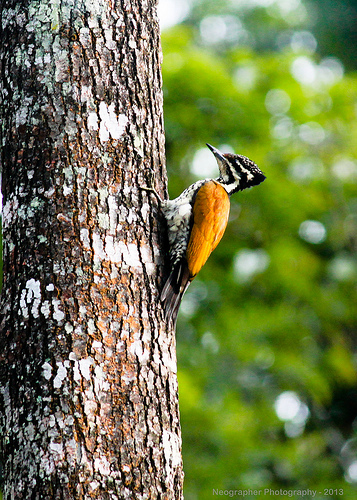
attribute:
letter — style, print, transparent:
[236, 489, 243, 497]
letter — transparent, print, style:
[210, 486, 218, 497]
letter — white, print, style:
[210, 486, 266, 498]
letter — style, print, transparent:
[273, 489, 280, 496]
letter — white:
[223, 489, 228, 497]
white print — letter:
[213, 487, 224, 496]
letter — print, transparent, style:
[263, 487, 268, 497]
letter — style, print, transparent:
[263, 486, 271, 497]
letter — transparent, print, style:
[219, 488, 223, 497]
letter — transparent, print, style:
[233, 486, 237, 497]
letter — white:
[228, 489, 237, 497]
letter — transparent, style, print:
[243, 483, 254, 499]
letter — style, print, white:
[210, 479, 341, 497]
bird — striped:
[133, 144, 267, 331]